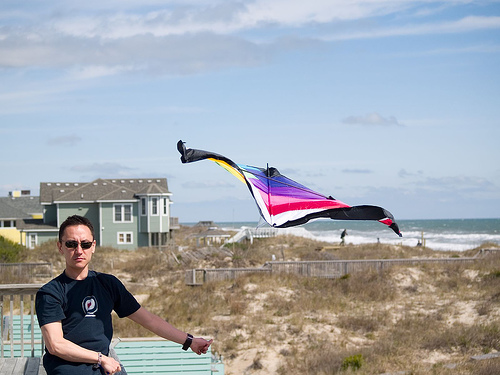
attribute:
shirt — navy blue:
[33, 271, 138, 365]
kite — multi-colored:
[176, 139, 403, 239]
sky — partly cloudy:
[1, 0, 498, 221]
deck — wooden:
[7, 318, 196, 374]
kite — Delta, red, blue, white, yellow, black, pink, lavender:
[178, 136, 408, 248]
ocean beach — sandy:
[107, 217, 397, 354]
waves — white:
[324, 226, 497, 249]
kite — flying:
[163, 135, 406, 253]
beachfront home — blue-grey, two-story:
[34, 174, 170, 252]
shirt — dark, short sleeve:
[41, 260, 150, 340]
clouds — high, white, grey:
[8, 2, 497, 102]